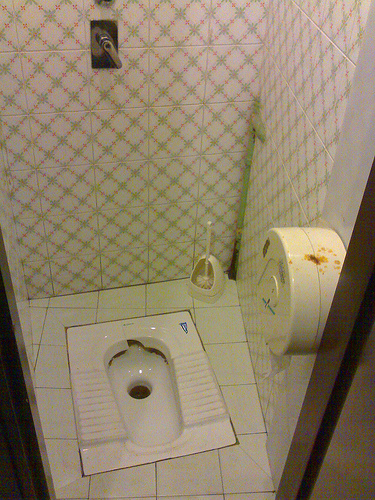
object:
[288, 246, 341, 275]
scum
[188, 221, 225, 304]
cleaner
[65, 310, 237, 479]
toilet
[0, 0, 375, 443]
tile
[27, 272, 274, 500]
tile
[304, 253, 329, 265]
speck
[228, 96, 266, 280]
pole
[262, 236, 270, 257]
hole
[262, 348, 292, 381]
paper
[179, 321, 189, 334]
symbol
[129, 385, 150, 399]
hole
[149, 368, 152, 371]
spot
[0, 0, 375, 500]
bathroom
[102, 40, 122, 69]
handle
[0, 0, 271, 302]
wall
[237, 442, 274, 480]
crack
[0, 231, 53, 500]
part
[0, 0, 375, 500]
doorway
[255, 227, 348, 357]
frame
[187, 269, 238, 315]
corner